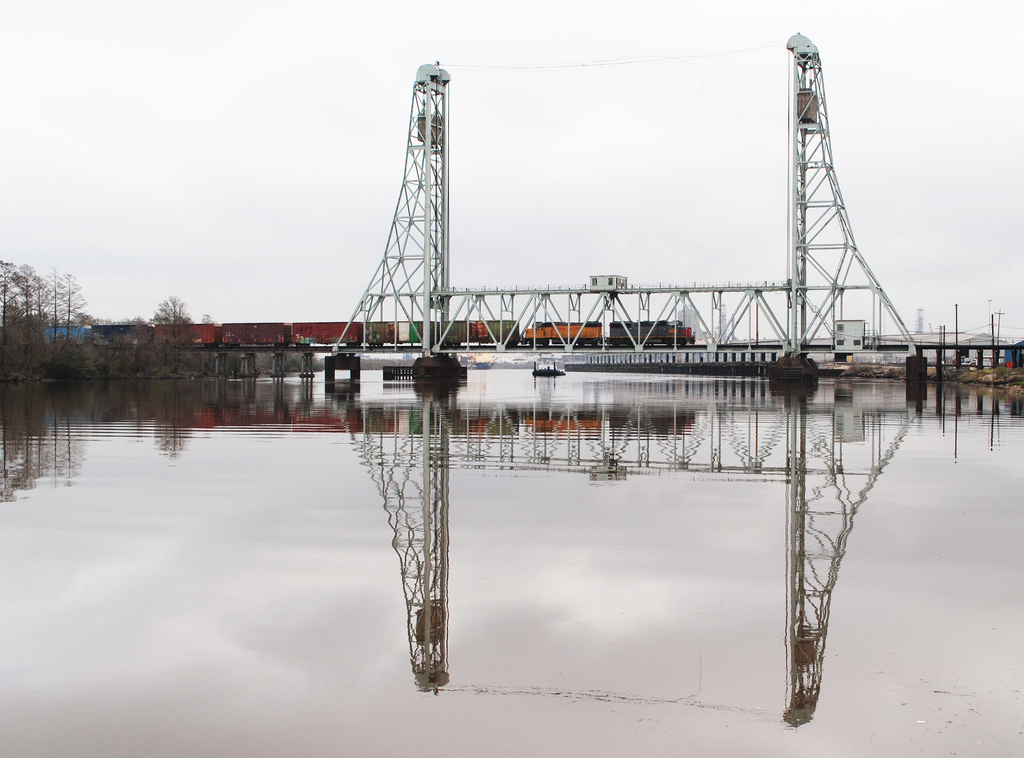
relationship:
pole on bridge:
[465, 292, 505, 355] [349, 276, 956, 362]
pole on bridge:
[550, 278, 573, 355] [319, 245, 911, 416]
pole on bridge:
[525, 297, 541, 362] [336, 213, 931, 471]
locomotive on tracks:
[148, 279, 678, 370] [0, 343, 1022, 381]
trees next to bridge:
[0, 259, 202, 377] [216, 31, 1024, 377]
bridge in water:
[216, 31, 1024, 377] [264, 377, 844, 606]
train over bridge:
[239, 223, 782, 392] [216, 31, 1024, 377]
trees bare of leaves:
[7, 267, 116, 495] [22, 282, 70, 362]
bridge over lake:
[216, 31, 1024, 377] [0, 347, 1022, 755]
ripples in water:
[50, 381, 206, 455] [3, 350, 1019, 755]